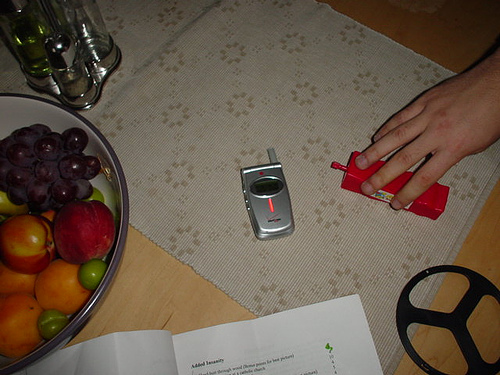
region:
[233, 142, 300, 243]
a cell phone on table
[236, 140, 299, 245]
red light on cell phone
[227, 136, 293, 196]
cell phone has an antenna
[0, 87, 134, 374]
bowl with fruits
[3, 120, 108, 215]
black grapes on bowl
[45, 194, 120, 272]
the peach is red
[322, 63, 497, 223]
hand over a red phone case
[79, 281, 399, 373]
white paper on table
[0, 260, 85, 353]
yellow peaches on bowl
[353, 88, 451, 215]
four fingers of hand are visible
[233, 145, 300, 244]
A silver cellphone.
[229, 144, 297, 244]
Verizon is printed on the cellphone.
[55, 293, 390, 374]
White papers are open on the table.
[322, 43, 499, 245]
A hand reaching for a red object.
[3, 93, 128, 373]
A bowl full of fruit.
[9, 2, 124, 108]
A glass object on the table.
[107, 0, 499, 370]
A tan patterned table runner.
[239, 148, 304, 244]
A red light on the top of the cellphone.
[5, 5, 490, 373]
The table is a light colored wood.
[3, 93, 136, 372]
Fruit in a large ceramic bowl.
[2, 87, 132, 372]
a bowl with fruits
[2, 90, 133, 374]
fruits in bowl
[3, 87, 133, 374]
bowl with fruits on table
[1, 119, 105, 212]
grapes in bowl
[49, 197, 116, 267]
peach in bowl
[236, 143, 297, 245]
cellphone on table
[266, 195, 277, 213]
light on the cellphone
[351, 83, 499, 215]
hand on table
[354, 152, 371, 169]
nail on finger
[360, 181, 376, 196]
nail on finger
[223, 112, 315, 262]
a silver cell phone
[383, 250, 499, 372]
a black sterring wheel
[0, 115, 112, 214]
a dust cluster of grapes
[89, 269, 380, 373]
a white piece of paper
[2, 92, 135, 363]
a bowl of fake fruit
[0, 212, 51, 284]
a yellow and red apple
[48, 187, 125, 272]
a red peach in bowl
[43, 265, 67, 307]
part of a orange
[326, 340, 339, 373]
numbers under a green symble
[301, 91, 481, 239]
a hand touching a red object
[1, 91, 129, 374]
Bowl of fruit on table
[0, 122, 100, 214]
Bunch of purple grapes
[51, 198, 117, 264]
Red piece of fruit in bowl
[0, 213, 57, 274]
Red and yellow apple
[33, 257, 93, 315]
Orange in fruit bowl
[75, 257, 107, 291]
Green lime in fruit bowl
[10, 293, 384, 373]
Open book on table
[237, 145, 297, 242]
Silver flip cell phone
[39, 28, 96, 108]
Glass pepper shaker on table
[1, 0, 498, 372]
Cream colored placemat with design